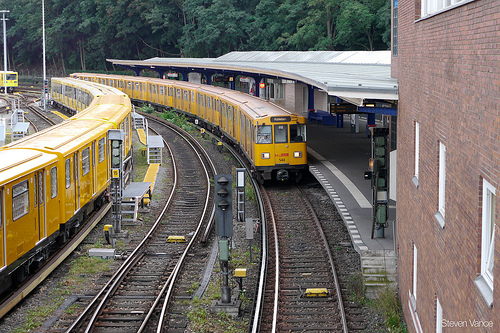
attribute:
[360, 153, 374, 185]
sign — big, orange, detour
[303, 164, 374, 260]
lines — broken, white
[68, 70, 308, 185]
train — yellow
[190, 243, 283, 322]
sign — Big, orange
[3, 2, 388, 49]
trees — green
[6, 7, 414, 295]
train station — train's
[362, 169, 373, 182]
sign — big, orange, detour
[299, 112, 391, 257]
platform — train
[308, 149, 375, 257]
white markings — caution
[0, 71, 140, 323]
train — curved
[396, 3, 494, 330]
wall — brick